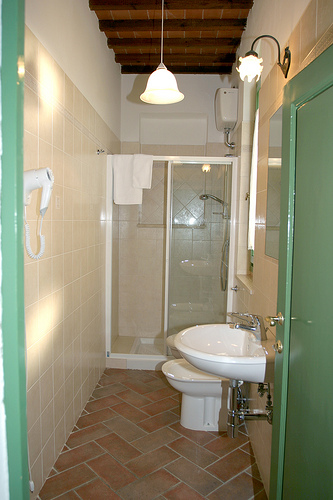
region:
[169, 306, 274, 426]
A WHITE BATHROOM SINK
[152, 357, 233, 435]
A WHITE TOILET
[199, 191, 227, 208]
A METAL SHOWER HEAD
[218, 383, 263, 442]
BATHROOM SINK PIPES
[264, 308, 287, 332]
BATHROOM DOOR KNOB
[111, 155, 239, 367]
SLIDING SHOWER DOORS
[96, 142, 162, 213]
WHITE TOWELS ON THE SHOWER DOOR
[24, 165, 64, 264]
A HAIR DRYER HANGING ON THE WALL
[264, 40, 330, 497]
A GREEN DOOR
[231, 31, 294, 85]
A BATHROOM LIGHT FIXTURE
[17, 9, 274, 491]
Bathroom is narrow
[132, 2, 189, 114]
Lamp hang from roof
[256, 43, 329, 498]
Bathroom has green door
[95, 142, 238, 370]
Shower has door of glass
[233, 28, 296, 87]
Lamp on wall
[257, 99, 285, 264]
Mirror under a wall lamp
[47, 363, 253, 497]
Floor is brown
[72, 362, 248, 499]
Floor is tiled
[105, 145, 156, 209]
Two towels on top of door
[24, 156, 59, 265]
Hair dryer is white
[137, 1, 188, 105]
hanging pendant light fixture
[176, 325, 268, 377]
white sink in a bathroom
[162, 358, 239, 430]
white porcelain toilet in a bathroom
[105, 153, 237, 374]
shower stall with glass doors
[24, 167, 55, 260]
wall-mounted hair dryer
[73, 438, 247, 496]
brown tiled floor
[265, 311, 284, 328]
silver doorknob on a green door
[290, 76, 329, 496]
green bathroom door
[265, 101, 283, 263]
mirror above the bathroom sink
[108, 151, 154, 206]
white bathroom linens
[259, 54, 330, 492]
a sea green bathroom door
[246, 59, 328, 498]
a sea green painted bathroom door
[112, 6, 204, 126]
a light hanging from the bathroom ceiling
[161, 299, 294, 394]
white bathroom sink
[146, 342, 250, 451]
white toilet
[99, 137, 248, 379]
a bathroom shower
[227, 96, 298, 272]
a bathroom mirror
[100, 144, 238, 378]
a white towel draped over a shower door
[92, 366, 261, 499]
brown tiled bathroom floor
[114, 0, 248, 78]
a wooden bathroom ceiling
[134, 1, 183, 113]
White light fixture hanging from ceiling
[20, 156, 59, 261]
White hair dryer mounted to wall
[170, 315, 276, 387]
White porcelain sink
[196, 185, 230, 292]
Hand held shower head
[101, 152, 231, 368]
walk-in shower with glass doors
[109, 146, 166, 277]
White towels draped over shower frame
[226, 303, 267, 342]
Silver bathroom sink faucet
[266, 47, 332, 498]
Green door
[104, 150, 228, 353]
Sliding glass doors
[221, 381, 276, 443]
metal plumbing pipes